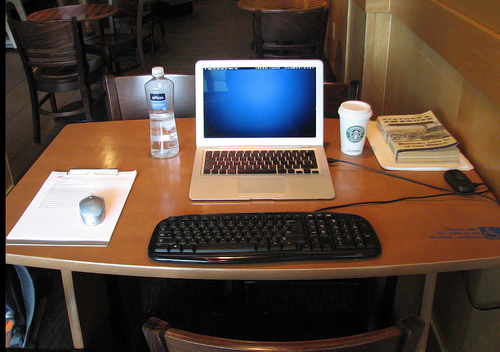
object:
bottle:
[143, 66, 180, 160]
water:
[150, 111, 180, 159]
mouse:
[79, 195, 106, 226]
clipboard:
[6, 167, 138, 247]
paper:
[5, 170, 139, 243]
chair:
[140, 311, 426, 352]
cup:
[337, 100, 373, 156]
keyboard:
[147, 211, 383, 264]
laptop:
[187, 58, 337, 200]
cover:
[377, 110, 461, 152]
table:
[6, 116, 500, 350]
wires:
[326, 157, 494, 197]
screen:
[203, 67, 316, 138]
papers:
[363, 118, 475, 171]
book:
[375, 109, 461, 164]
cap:
[150, 66, 165, 80]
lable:
[150, 93, 168, 112]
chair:
[6, 2, 116, 146]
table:
[237, 0, 330, 13]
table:
[27, 2, 121, 24]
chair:
[253, 6, 338, 83]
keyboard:
[202, 149, 322, 174]